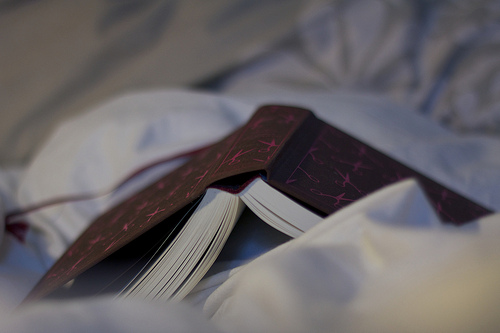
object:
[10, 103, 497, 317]
book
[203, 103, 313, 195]
spine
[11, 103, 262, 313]
front cover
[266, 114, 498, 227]
back cover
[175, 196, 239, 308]
pages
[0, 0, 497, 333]
bed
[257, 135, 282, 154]
scissors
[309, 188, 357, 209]
scissors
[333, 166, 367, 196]
scissors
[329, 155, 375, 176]
scissors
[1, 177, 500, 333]
sheet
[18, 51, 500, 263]
pillow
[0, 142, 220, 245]
bookmark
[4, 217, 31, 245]
end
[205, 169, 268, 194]
gap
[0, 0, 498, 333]
fabric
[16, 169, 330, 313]
top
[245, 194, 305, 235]
gaps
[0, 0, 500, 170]
sheet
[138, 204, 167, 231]
pattern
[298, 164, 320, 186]
pattern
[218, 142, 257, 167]
pattern